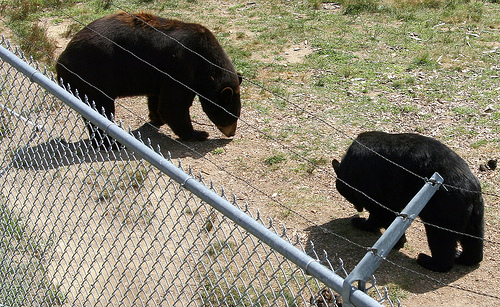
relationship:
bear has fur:
[56, 14, 243, 150] [56, 13, 243, 148]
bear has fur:
[330, 132, 485, 272] [331, 131, 485, 274]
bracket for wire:
[341, 171, 445, 303] [106, 2, 499, 200]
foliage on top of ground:
[1, 0, 499, 119] [4, 1, 499, 306]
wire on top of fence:
[106, 2, 499, 200] [0, 35, 402, 306]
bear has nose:
[56, 14, 243, 150] [228, 131, 236, 137]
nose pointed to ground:
[228, 131, 236, 137] [4, 1, 499, 306]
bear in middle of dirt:
[330, 132, 485, 272] [1, 154, 499, 304]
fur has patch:
[56, 13, 243, 148] [103, 12, 176, 28]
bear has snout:
[56, 14, 243, 150] [213, 122, 238, 137]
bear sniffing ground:
[56, 14, 243, 150] [4, 1, 499, 306]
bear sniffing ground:
[330, 132, 485, 272] [4, 1, 499, 306]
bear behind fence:
[56, 14, 243, 150] [0, 35, 402, 306]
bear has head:
[56, 14, 243, 150] [200, 71, 244, 137]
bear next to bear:
[56, 14, 243, 150] [330, 132, 485, 272]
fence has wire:
[0, 35, 402, 306] [106, 2, 499, 200]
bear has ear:
[56, 14, 243, 150] [221, 86, 234, 100]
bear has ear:
[56, 14, 243, 150] [237, 72, 243, 85]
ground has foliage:
[4, 1, 499, 306] [1, 0, 499, 119]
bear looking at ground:
[56, 14, 243, 150] [4, 1, 499, 306]